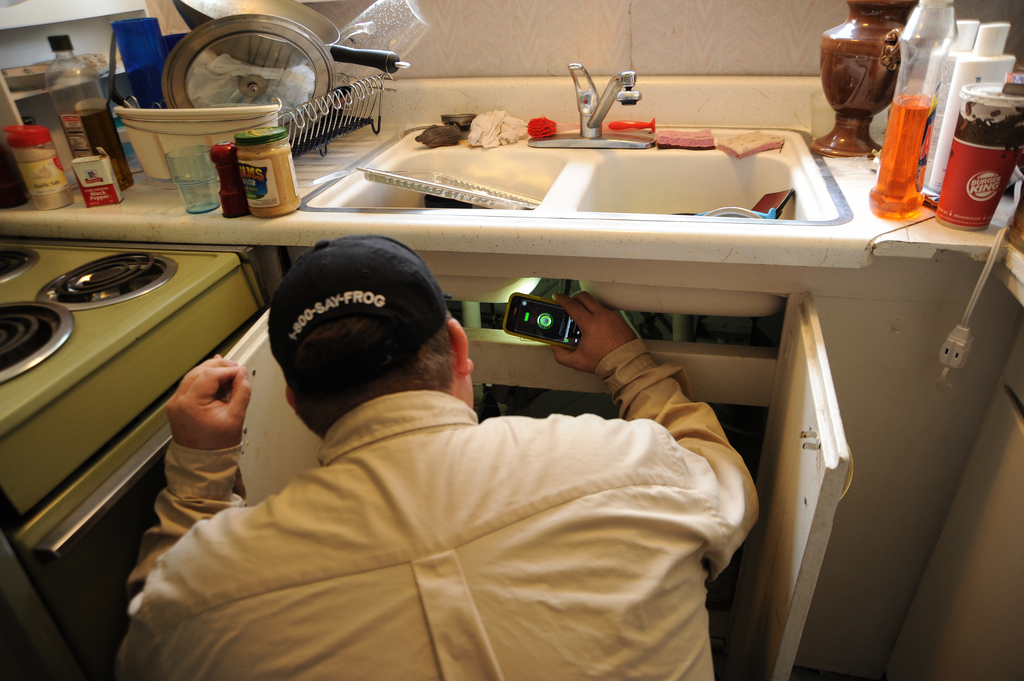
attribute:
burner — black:
[1, 241, 37, 283]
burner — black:
[38, 251, 162, 312]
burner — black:
[0, 295, 80, 382]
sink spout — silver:
[560, 58, 643, 136]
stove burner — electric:
[48, 250, 175, 311]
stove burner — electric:
[0, 242, 33, 280]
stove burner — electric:
[0, 301, 78, 387]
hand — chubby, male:
[172, 343, 256, 449]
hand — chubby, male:
[556, 294, 637, 377]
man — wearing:
[115, 237, 761, 678]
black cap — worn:
[268, 237, 453, 397]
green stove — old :
[0, 229, 263, 673]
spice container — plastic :
[7, 115, 68, 210]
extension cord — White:
[933, 221, 1017, 383]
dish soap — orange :
[869, 99, 936, 223]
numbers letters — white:
[286, 287, 392, 345]